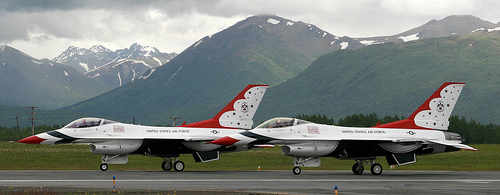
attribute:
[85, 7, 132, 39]
clouds — white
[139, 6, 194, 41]
sky — blue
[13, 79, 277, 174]
jet — red, white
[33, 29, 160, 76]
clouds — white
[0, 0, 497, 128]
sky — blue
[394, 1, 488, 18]
clouds — white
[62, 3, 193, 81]
clouds — white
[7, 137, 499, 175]
grass — green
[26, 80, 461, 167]
jets — white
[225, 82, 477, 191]
plane — white, red, blue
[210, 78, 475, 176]
jet — red, white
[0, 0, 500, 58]
clouds — white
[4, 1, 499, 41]
sky — blue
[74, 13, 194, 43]
clouds — white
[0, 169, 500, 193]
ground — paved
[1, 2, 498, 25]
clouds — white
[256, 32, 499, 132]
mountains — green, rocky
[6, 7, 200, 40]
clouds — white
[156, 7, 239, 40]
clouds — white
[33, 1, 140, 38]
clouds — white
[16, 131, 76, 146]
stripes — red, white, blue, angled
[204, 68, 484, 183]
jet — white, red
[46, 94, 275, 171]
jet plane — blue, red, white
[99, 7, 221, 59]
sky — blue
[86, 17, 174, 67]
clouds — white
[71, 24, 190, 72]
sky — blue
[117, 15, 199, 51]
sky — blue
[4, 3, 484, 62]
sky — blue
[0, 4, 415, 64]
sky — blue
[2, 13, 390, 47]
sky — blue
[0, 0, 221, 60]
clouds — white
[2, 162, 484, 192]
ground — gray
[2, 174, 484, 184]
line — white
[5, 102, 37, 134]
poles — angled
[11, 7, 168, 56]
sky — blue